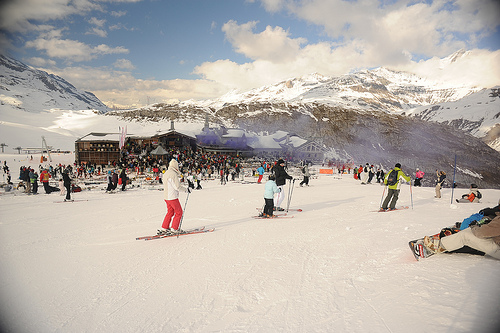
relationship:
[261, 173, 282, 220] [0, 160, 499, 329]
person on snow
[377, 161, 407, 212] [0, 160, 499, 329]
person on snow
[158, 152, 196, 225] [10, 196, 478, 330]
person on snow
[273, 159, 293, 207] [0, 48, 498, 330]
person on snow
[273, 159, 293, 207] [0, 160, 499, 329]
person on snow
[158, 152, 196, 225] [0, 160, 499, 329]
person on snow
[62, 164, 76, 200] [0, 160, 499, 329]
skier on snow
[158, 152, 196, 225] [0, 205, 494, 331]
person standing in snow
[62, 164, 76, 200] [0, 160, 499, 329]
skier standing in snow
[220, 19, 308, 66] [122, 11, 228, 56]
cloud hanging in sky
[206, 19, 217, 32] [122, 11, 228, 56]
cloud hanging in sky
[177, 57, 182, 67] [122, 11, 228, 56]
cloud hanging in sky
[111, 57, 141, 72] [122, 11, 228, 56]
cloud hanging in sky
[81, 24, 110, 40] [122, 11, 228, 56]
cloud hanging in sky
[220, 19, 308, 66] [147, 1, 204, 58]
cloud hanging in blue sky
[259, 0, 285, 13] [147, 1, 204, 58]
cloud hanging in blue sky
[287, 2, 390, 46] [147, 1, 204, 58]
cloud hanging in blue sky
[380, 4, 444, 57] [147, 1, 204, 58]
cloud hanging in blue sky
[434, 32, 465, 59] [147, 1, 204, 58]
cloud hanging in blue sky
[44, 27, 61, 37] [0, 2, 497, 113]
cloud hanging in sky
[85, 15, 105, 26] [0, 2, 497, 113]
cloud hanging in sky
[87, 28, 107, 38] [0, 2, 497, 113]
cloud hanging in sky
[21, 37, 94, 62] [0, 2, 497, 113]
cloud hanging in sky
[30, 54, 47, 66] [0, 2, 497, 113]
cloud hanging in sky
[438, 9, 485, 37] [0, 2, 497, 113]
cloud hanging in sky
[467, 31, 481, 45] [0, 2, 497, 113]
cloud hanging in sky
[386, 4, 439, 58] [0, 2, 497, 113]
cloud hanging in sky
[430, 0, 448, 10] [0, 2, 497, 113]
cloud hanging in sky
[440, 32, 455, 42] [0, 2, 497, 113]
cloud hanging in sky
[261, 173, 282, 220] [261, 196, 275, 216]
person wearing pants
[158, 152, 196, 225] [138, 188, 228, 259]
person on hillside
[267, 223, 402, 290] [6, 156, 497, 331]
snow on hillside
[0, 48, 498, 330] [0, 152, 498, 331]
snow on ground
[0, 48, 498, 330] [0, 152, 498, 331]
snow covering ground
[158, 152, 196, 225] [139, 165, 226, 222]
person wearing jacket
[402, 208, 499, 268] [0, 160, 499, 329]
skateboarder sitting resting in snow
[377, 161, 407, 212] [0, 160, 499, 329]
person sitting resting in snow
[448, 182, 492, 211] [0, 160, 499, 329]
skateboarder sitting resting in snow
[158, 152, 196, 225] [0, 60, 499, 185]
person sitting resting in snow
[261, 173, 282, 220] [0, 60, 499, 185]
person sitting resting in snow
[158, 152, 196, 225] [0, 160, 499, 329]
person in snow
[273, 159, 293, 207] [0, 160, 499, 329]
person in snow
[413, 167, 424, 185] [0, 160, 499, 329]
skier in snow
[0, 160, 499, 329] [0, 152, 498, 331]
snow covering ground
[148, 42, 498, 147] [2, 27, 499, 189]
snow covering mountain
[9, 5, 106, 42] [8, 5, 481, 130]
white clouds in sky